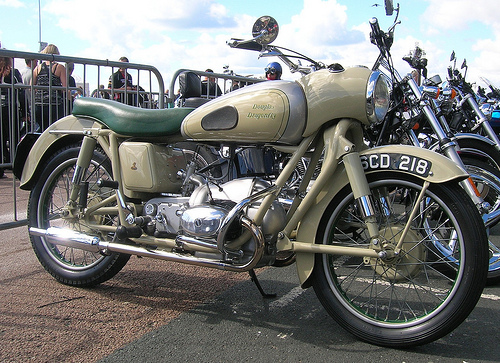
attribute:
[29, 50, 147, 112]
barrier — metal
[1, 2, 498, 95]
sky — blue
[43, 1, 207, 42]
cloud — white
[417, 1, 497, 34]
cloud — white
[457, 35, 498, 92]
cloud — white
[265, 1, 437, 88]
cloud — white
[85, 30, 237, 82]
cloud — white